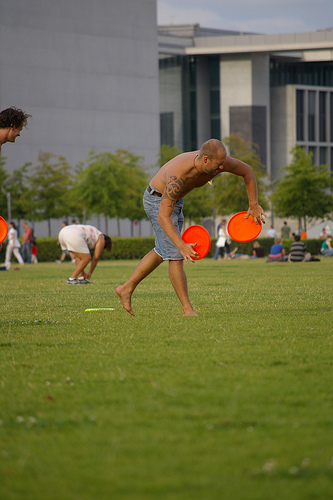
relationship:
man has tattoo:
[112, 135, 269, 318] [161, 172, 189, 204]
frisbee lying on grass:
[81, 304, 117, 315] [0, 257, 331, 500]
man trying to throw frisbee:
[112, 135, 269, 318] [224, 210, 264, 244]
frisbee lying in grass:
[81, 304, 117, 315] [0, 257, 331, 500]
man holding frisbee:
[112, 135, 269, 318] [179, 224, 210, 261]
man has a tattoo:
[112, 135, 269, 318] [161, 172, 189, 204]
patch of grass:
[0, 315, 80, 334] [0, 257, 331, 500]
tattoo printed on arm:
[161, 172, 189, 204] [157, 162, 200, 265]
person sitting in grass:
[287, 231, 309, 264] [0, 257, 331, 500]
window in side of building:
[291, 88, 308, 144] [159, 22, 331, 216]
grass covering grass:
[0, 257, 331, 500] [0, 257, 331, 500]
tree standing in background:
[267, 146, 331, 230] [1, 0, 331, 259]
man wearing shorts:
[112, 135, 269, 318] [141, 181, 188, 262]